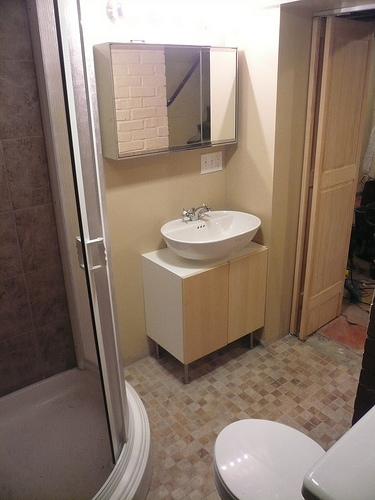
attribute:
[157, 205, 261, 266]
sink — large, white, ceramic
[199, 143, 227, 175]
outlets — white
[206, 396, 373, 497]
toilet — white, ceramic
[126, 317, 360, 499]
floor — cream, beige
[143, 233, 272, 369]
cabinet — white, wooden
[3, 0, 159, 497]
stall — large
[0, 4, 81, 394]
tiles — dark brown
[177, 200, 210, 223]
faucet — silver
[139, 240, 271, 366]
cabinet — white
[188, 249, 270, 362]
doors — wooden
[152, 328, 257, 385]
legs — silver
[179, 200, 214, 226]
handle — silver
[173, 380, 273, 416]
floor — brown, white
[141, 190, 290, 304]
sink — white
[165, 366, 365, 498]
toilet seat — closed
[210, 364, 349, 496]
toilet seat — closed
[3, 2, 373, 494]
bathroom — bright, neat, clean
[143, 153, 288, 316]
bathroom sink — oval shaped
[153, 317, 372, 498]
toilet — white, porcelain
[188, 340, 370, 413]
bathroom floor — tiles, mixed colors, beige, brown, tan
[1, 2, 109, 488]
door — sliding glass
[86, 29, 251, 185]
mirror — large, rectangular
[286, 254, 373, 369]
doorstep — an entrance, damaged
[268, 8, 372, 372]
door — wooden, folding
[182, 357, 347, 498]
toilet cover — down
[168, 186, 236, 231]
faucet — silver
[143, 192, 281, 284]
sink — white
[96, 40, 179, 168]
bruck — white painted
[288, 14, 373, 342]
door — tall, light brown, wooden, folding, beige, wood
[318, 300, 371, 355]
rug — orange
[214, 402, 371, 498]
toilet — white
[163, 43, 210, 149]
mirror — clean, glass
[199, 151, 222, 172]
light switch — multiple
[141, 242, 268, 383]
cabinet — double door, beige, white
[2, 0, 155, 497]
shower area — enclosed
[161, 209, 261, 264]
wash basin — white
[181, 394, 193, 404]
tile — brown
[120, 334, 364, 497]
floor — beige, brown, tiled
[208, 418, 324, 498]
commode — white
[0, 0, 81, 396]
wall — grey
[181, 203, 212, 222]
faucet — chrome, silver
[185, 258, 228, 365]
door — wood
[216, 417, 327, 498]
toilet top — closed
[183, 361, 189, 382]
leg — iron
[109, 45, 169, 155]
wall — brick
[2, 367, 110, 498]
floor — clean